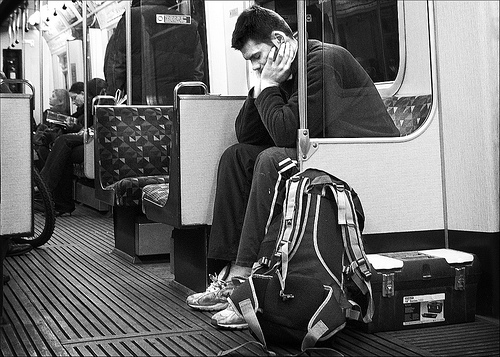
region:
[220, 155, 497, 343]
bags placed on floor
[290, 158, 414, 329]
bags placed on floor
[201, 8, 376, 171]
man with hands on face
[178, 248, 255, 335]
feet below the man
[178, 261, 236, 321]
shoe on the man's feet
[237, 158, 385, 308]
backpack next to the man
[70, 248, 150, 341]
ground below the man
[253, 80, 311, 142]
long sleeve of the shirt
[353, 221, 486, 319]
case next to the backpack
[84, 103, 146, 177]
seat next to the man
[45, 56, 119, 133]
people sitting on the train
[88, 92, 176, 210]
empty seat next to man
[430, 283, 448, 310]
the luggage is black and white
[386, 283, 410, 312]
the luggage is black and white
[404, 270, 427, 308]
the luggage is black and white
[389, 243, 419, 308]
the luggage is black and white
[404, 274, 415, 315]
the luggage is black and white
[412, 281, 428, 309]
the luggage is black and white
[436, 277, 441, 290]
the luggage is black and white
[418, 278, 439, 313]
the luggage is black and white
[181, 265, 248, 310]
the shoe of a man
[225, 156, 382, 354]
a tall backpack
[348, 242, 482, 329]
a big tool box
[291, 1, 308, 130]
a short gray pole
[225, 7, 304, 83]
the head of a man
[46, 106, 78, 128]
a magazine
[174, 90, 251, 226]
the back of a seat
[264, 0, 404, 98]
the window of a bus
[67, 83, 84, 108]
the head of a woman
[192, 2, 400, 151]
Man sleeping in the subway.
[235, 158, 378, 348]
backpack sitting on the ground.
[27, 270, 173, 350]
Flooring covered in strips of metal.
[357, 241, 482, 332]
Large toolbox sitting on the floor.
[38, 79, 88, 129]
Two women riding in the subway.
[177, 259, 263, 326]
Sneakers being worn on a man's feet.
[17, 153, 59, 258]
Front wheel of a bicycle.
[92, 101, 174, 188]
Multi-colored fabric of the subway seating.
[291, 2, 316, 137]
Metal pole used to hold on to.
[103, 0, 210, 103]
Person standing up while riding the subway.